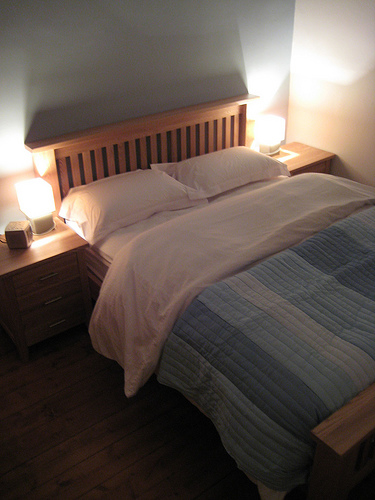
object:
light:
[13, 176, 60, 234]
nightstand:
[0, 214, 92, 361]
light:
[256, 110, 285, 157]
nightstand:
[269, 141, 335, 174]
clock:
[5, 220, 34, 250]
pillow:
[58, 168, 207, 247]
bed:
[27, 90, 374, 500]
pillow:
[150, 144, 292, 200]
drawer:
[25, 305, 87, 346]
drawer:
[20, 273, 89, 324]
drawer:
[12, 251, 84, 295]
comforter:
[89, 173, 375, 490]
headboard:
[23, 94, 261, 224]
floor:
[0, 322, 257, 497]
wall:
[0, 0, 300, 236]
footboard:
[302, 382, 374, 498]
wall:
[286, 1, 373, 188]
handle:
[48, 317, 66, 330]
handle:
[46, 293, 63, 304]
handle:
[41, 271, 57, 283]